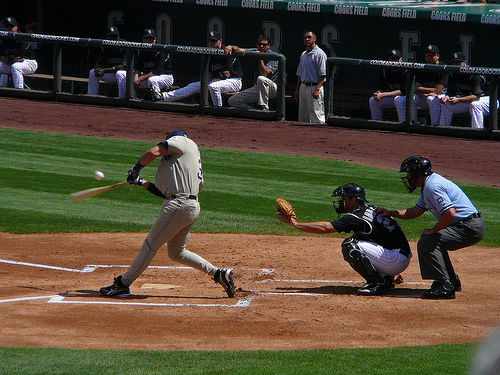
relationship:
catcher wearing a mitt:
[271, 181, 395, 287] [272, 193, 298, 228]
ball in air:
[93, 168, 104, 181] [66, 102, 94, 122]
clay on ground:
[239, 137, 268, 159] [193, 217, 271, 272]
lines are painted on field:
[40, 260, 65, 278] [190, 336, 264, 373]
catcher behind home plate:
[271, 181, 395, 287] [149, 276, 231, 306]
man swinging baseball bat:
[299, 36, 334, 122] [63, 182, 111, 198]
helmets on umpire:
[432, 44, 455, 57] [403, 161, 456, 289]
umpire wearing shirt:
[403, 161, 456, 289] [428, 181, 455, 206]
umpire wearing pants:
[403, 161, 456, 289] [305, 100, 316, 114]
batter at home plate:
[128, 114, 228, 294] [149, 276, 231, 306]